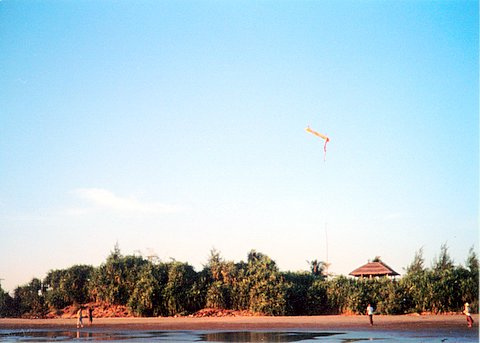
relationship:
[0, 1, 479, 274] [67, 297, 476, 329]
sky above people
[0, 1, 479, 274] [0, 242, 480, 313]
sky above trees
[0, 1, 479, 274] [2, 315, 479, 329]
sky above beach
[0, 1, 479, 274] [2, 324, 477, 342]
sky above water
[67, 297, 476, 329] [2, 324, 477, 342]
people by water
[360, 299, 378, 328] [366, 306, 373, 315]
person in shirt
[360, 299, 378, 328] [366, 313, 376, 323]
person in pants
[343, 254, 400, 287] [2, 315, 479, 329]
building on beach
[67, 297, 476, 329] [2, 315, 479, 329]
people on beach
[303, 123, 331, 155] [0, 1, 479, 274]
kite in sky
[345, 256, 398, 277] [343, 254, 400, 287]
roof on building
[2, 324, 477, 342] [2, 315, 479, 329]
water near beach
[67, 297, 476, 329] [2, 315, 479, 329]
people walking on beach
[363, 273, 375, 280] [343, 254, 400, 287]
pole on building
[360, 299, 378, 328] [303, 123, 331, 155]
person flying kite